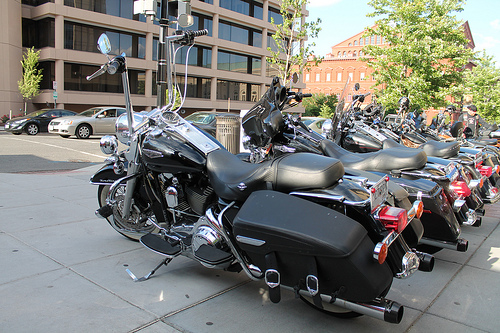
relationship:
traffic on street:
[2, 83, 200, 134] [56, 72, 444, 258]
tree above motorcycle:
[370, 15, 458, 100] [167, 81, 445, 312]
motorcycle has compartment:
[83, 12, 438, 325] [257, 189, 340, 274]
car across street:
[7, 67, 194, 182] [56, 72, 444, 258]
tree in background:
[370, 15, 458, 100] [306, 29, 474, 169]